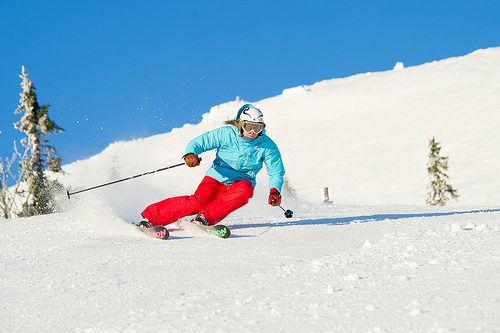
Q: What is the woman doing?
A: Skiing.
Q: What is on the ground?
A: Snow.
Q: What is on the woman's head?
A: Helmet.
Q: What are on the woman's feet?
A: Skis.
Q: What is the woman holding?
A: Ski poles.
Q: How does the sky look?
A: Clear and blue.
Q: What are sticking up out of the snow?
A: Trees.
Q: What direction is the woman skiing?
A: Downhill.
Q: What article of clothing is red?
A: Pants.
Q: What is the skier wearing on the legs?
A: Pants.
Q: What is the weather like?
A: Clear.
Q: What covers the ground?
A: Snow.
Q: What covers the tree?
A: Snow.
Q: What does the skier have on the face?
A: Glasses.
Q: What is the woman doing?
A: Skiing.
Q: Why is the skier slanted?
A: To turn.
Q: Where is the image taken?
A: Snow.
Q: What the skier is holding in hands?
A: Black poles.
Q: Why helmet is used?
A: Safety.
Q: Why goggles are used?
A: Safety eyes.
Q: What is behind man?
A: Snow.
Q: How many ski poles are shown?
A: Two.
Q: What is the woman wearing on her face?
A: Goggles.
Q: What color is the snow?
A: White.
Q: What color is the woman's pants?
A: Red.